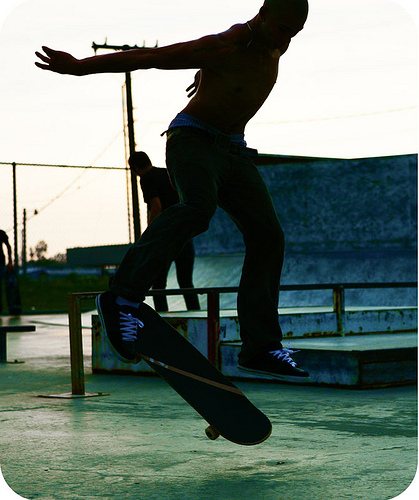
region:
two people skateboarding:
[93, 12, 357, 478]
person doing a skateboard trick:
[111, 6, 327, 442]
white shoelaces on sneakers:
[113, 306, 150, 356]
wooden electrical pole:
[80, 27, 182, 255]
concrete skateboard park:
[37, 161, 373, 460]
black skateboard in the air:
[120, 298, 270, 462]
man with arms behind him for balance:
[73, 6, 302, 171]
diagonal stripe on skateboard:
[126, 324, 246, 400]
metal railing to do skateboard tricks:
[59, 250, 403, 397]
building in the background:
[28, 233, 148, 301]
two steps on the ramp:
[298, 257, 389, 390]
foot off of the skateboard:
[228, 332, 316, 422]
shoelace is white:
[100, 305, 170, 345]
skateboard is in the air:
[90, 286, 339, 484]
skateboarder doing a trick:
[61, 219, 344, 484]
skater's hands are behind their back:
[27, 25, 223, 116]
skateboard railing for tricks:
[305, 272, 418, 301]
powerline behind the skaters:
[84, 18, 179, 249]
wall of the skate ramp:
[271, 147, 415, 262]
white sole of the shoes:
[88, 293, 136, 369]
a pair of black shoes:
[110, 236, 408, 436]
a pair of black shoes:
[78, 264, 323, 481]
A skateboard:
[134, 292, 269, 498]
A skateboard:
[159, 307, 236, 486]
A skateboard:
[163, 252, 216, 428]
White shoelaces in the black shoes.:
[116, 294, 144, 350]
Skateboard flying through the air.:
[132, 299, 275, 454]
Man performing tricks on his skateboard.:
[32, 2, 328, 448]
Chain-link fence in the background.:
[5, 158, 107, 236]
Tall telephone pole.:
[88, 31, 157, 230]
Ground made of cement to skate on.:
[37, 413, 188, 484]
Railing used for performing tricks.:
[306, 276, 417, 293]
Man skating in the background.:
[120, 144, 210, 309]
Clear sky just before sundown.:
[8, 84, 98, 149]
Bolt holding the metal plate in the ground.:
[93, 389, 106, 397]